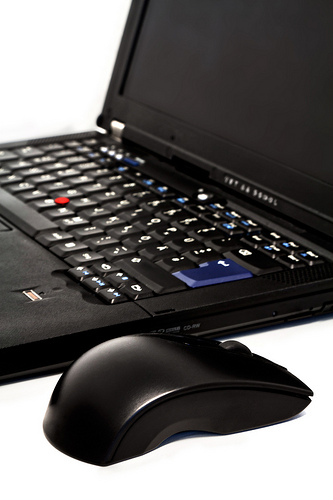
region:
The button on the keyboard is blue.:
[174, 261, 254, 288]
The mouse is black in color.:
[42, 337, 318, 469]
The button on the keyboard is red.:
[53, 194, 68, 204]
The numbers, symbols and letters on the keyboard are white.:
[14, 127, 305, 301]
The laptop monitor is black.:
[103, 0, 329, 224]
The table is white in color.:
[293, 329, 330, 343]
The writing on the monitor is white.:
[220, 173, 278, 207]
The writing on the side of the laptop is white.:
[154, 320, 202, 332]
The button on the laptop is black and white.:
[228, 241, 282, 273]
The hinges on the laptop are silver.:
[103, 117, 126, 142]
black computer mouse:
[43, 333, 313, 464]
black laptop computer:
[2, 0, 328, 376]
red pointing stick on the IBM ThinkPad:
[51, 195, 64, 201]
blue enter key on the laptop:
[173, 252, 247, 282]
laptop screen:
[93, 0, 327, 235]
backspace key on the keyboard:
[223, 246, 279, 272]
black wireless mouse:
[28, 327, 309, 461]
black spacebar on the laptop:
[0, 190, 58, 235]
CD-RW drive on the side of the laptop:
[148, 289, 330, 339]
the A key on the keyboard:
[141, 242, 174, 260]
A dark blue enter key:
[169, 257, 253, 288]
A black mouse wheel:
[218, 339, 254, 355]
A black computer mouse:
[41, 329, 315, 469]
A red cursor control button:
[52, 195, 71, 206]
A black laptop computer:
[0, 0, 332, 388]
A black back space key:
[219, 245, 284, 276]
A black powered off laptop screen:
[116, 0, 332, 186]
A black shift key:
[109, 253, 188, 295]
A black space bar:
[0, 182, 63, 239]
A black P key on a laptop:
[145, 224, 190, 244]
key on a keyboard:
[117, 275, 159, 302]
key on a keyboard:
[98, 283, 127, 305]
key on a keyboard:
[81, 271, 110, 290]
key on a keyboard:
[65, 259, 97, 279]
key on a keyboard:
[65, 246, 105, 267]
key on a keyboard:
[51, 236, 90, 255]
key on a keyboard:
[37, 228, 75, 243]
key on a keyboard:
[166, 253, 252, 290]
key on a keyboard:
[221, 245, 285, 278]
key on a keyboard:
[187, 224, 226, 239]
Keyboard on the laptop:
[24, 135, 331, 380]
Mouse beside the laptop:
[32, 296, 331, 463]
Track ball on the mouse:
[218, 338, 268, 375]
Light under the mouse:
[156, 425, 250, 486]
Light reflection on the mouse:
[118, 362, 186, 436]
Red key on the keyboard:
[52, 189, 70, 208]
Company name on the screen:
[206, 167, 314, 273]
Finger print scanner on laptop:
[16, 286, 42, 304]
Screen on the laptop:
[138, 60, 320, 203]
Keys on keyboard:
[86, 272, 128, 302]